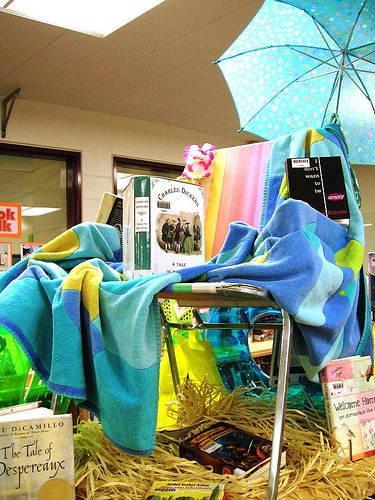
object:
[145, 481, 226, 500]
book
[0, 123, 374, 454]
towel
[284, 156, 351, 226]
book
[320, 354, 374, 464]
book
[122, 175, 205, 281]
book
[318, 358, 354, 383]
pink square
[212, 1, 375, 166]
blue umbrella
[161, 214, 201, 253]
person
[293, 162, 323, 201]
black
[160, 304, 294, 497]
legs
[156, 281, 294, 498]
beach chair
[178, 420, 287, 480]
book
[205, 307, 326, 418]
innertube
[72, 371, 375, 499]
hay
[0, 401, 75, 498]
book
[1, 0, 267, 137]
ceiling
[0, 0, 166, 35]
light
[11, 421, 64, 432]
author name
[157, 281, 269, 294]
fabric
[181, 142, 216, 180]
flower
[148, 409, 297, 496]
pile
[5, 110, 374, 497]
display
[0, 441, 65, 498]
title